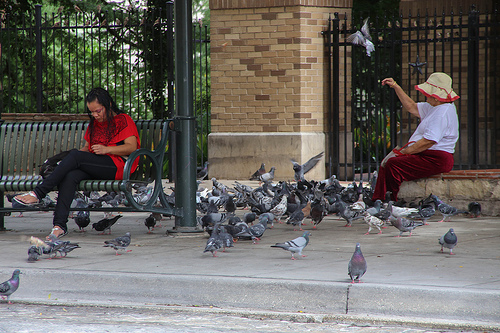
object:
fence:
[0, 14, 208, 115]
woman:
[11, 86, 140, 241]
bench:
[0, 118, 182, 232]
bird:
[227, 220, 258, 243]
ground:
[0, 213, 497, 332]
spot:
[246, 236, 260, 243]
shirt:
[83, 113, 138, 179]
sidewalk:
[1, 213, 498, 298]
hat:
[411, 72, 459, 101]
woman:
[370, 70, 461, 213]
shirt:
[410, 101, 458, 154]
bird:
[0, 268, 22, 303]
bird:
[386, 215, 425, 237]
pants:
[34, 153, 128, 228]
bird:
[346, 242, 366, 284]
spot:
[351, 251, 363, 260]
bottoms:
[400, 148, 453, 174]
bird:
[88, 216, 124, 233]